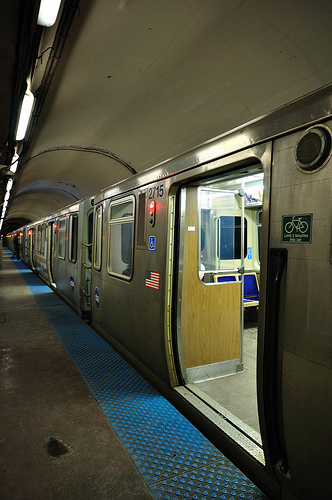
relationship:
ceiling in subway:
[0, 0, 331, 237] [14, 193, 280, 359]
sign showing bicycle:
[279, 211, 315, 244] [283, 213, 308, 234]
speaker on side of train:
[286, 125, 327, 174] [57, 169, 326, 386]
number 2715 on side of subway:
[137, 183, 173, 200] [1, 0, 331, 497]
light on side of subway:
[149, 202, 154, 210] [1, 0, 331, 497]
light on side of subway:
[53, 223, 59, 230] [1, 0, 331, 497]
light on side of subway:
[26, 228, 32, 235] [1, 0, 331, 497]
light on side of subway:
[17, 230, 25, 238] [1, 0, 331, 497]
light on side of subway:
[12, 232, 18, 237] [1, 0, 331, 497]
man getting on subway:
[11, 232, 22, 261] [0, 81, 331, 496]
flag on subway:
[143, 268, 161, 289] [0, 81, 331, 496]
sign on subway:
[148, 235, 156, 251] [17, 101, 321, 357]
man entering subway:
[7, 228, 32, 264] [0, 81, 331, 496]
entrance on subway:
[167, 154, 277, 465] [1, 0, 331, 497]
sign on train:
[280, 213, 312, 243] [4, 194, 300, 322]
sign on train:
[146, 234, 161, 254] [5, 121, 327, 471]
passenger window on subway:
[106, 196, 137, 279] [0, 81, 331, 496]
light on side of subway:
[147, 202, 154, 210] [1, 0, 331, 497]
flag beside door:
[145, 270, 159, 292] [163, 154, 266, 470]